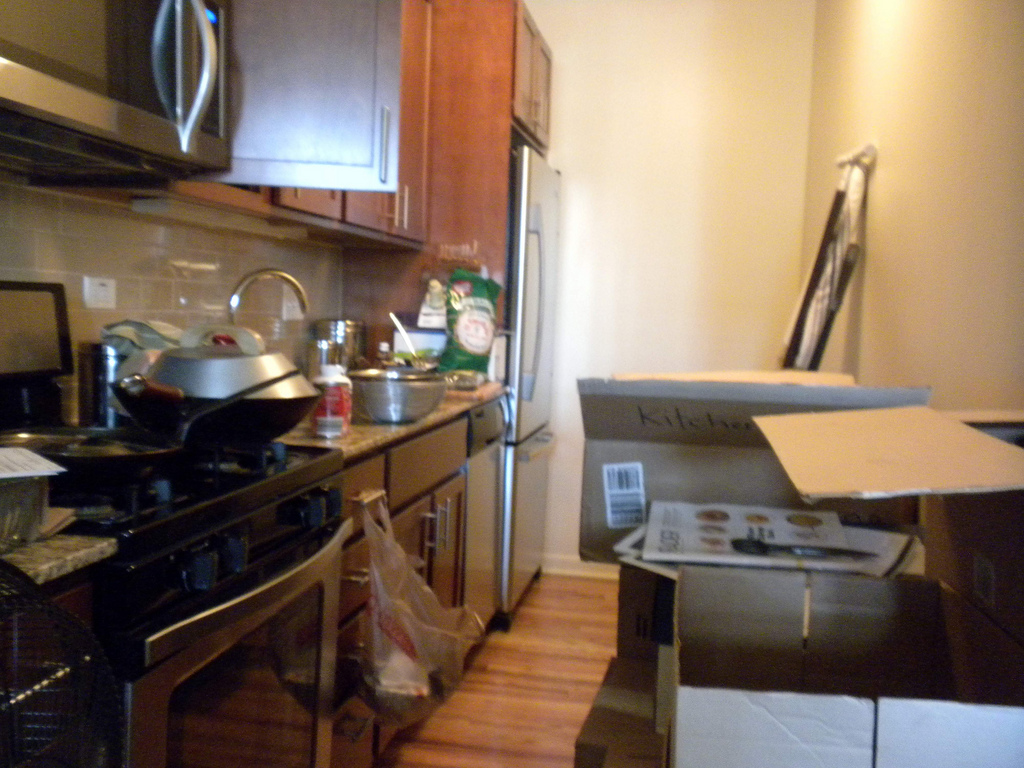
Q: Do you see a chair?
A: No, there are no chairs.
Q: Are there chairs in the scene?
A: No, there are no chairs.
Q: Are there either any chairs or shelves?
A: No, there are no chairs or shelves.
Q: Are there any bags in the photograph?
A: Yes, there is a bag.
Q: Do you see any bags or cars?
A: Yes, there is a bag.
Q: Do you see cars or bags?
A: Yes, there is a bag.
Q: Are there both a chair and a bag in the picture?
A: No, there is a bag but no chairs.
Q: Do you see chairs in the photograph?
A: No, there are no chairs.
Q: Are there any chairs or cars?
A: No, there are no chairs or cars.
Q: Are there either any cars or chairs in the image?
A: No, there are no chairs or cars.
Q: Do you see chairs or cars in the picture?
A: No, there are no chairs or cars.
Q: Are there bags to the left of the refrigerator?
A: Yes, there is a bag to the left of the refrigerator.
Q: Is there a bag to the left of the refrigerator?
A: Yes, there is a bag to the left of the refrigerator.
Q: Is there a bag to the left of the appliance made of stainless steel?
A: Yes, there is a bag to the left of the refrigerator.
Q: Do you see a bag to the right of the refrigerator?
A: No, the bag is to the left of the refrigerator.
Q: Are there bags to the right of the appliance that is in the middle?
A: No, the bag is to the left of the refrigerator.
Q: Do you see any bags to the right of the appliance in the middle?
A: No, the bag is to the left of the refrigerator.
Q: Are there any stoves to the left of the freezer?
A: No, there is a bag to the left of the freezer.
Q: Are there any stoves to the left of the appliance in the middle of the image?
A: No, there is a bag to the left of the freezer.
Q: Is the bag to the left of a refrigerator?
A: Yes, the bag is to the left of a refrigerator.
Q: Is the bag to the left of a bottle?
A: No, the bag is to the left of a refrigerator.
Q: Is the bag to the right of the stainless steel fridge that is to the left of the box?
A: No, the bag is to the left of the refrigerator.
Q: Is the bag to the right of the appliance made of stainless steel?
A: No, the bag is to the left of the refrigerator.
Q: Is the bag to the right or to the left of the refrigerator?
A: The bag is to the left of the refrigerator.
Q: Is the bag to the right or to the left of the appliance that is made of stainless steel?
A: The bag is to the left of the refrigerator.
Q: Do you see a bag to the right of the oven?
A: Yes, there is a bag to the right of the oven.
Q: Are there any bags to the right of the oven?
A: Yes, there is a bag to the right of the oven.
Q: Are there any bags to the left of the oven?
A: No, the bag is to the right of the oven.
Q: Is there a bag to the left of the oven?
A: No, the bag is to the right of the oven.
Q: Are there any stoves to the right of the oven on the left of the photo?
A: No, there is a bag to the right of the oven.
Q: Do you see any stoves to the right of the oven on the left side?
A: No, there is a bag to the right of the oven.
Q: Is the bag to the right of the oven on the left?
A: Yes, the bag is to the right of the oven.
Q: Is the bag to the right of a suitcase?
A: No, the bag is to the right of the oven.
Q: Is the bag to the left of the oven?
A: No, the bag is to the right of the oven.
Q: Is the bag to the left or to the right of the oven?
A: The bag is to the right of the oven.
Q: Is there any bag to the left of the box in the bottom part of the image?
A: Yes, there is a bag to the left of the box.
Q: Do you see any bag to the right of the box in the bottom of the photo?
A: No, the bag is to the left of the box.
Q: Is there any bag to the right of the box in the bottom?
A: No, the bag is to the left of the box.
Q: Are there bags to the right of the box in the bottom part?
A: No, the bag is to the left of the box.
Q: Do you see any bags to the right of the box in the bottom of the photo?
A: No, the bag is to the left of the box.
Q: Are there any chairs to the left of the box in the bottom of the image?
A: No, there is a bag to the left of the box.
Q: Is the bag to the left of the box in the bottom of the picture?
A: Yes, the bag is to the left of the box.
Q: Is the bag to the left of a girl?
A: No, the bag is to the left of the box.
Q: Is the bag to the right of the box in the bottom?
A: No, the bag is to the left of the box.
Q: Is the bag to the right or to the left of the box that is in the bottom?
A: The bag is to the left of the box.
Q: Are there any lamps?
A: No, there are no lamps.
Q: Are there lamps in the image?
A: No, there are no lamps.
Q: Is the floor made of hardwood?
A: Yes, the floor is made of hardwood.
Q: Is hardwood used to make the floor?
A: Yes, the floor is made of hardwood.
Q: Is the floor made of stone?
A: No, the floor is made of hardwood.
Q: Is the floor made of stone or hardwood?
A: The floor is made of hardwood.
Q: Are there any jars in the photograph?
A: No, there are no jars.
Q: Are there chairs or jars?
A: No, there are no jars or chairs.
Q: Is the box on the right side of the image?
A: Yes, the box is on the right of the image.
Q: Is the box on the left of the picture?
A: No, the box is on the right of the image.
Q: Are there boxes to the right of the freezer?
A: Yes, there is a box to the right of the freezer.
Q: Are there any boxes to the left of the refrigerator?
A: No, the box is to the right of the refrigerator.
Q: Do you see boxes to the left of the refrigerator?
A: No, the box is to the right of the refrigerator.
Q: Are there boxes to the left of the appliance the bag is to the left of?
A: No, the box is to the right of the refrigerator.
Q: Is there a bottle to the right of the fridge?
A: No, there is a box to the right of the fridge.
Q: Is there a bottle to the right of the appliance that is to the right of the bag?
A: No, there is a box to the right of the fridge.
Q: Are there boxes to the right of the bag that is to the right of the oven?
A: Yes, there is a box to the right of the bag.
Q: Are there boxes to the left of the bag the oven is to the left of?
A: No, the box is to the right of the bag.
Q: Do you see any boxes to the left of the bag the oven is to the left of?
A: No, the box is to the right of the bag.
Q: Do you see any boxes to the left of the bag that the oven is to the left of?
A: No, the box is to the right of the bag.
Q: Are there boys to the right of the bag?
A: No, there is a box to the right of the bag.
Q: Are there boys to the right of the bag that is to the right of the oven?
A: No, there is a box to the right of the bag.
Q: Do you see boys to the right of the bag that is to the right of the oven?
A: No, there is a box to the right of the bag.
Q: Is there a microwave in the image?
A: Yes, there is a microwave.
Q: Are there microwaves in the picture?
A: Yes, there is a microwave.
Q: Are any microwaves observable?
A: Yes, there is a microwave.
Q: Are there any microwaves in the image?
A: Yes, there is a microwave.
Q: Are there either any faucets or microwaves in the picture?
A: Yes, there is a microwave.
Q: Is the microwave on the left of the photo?
A: Yes, the microwave is on the left of the image.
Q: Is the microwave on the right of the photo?
A: No, the microwave is on the left of the image.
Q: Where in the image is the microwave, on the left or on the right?
A: The microwave is on the left of the image.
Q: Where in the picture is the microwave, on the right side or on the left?
A: The microwave is on the left of the image.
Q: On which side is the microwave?
A: The microwave is on the left of the image.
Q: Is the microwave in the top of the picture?
A: Yes, the microwave is in the top of the image.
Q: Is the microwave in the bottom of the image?
A: No, the microwave is in the top of the image.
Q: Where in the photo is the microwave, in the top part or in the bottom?
A: The microwave is in the top of the image.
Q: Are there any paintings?
A: No, there are no paintings.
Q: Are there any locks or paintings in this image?
A: No, there are no paintings or locks.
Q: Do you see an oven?
A: Yes, there is an oven.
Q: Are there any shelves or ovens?
A: Yes, there is an oven.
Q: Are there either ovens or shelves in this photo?
A: Yes, there is an oven.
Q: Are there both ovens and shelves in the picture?
A: No, there is an oven but no shelves.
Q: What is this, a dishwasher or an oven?
A: This is an oven.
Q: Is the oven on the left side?
A: Yes, the oven is on the left of the image.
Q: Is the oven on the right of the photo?
A: No, the oven is on the left of the image.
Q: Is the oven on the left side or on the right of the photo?
A: The oven is on the left of the image.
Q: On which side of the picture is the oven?
A: The oven is on the left of the image.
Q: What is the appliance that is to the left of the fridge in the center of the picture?
A: The appliance is an oven.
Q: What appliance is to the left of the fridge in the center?
A: The appliance is an oven.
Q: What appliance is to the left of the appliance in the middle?
A: The appliance is an oven.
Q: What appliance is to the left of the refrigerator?
A: The appliance is an oven.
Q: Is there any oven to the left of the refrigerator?
A: Yes, there is an oven to the left of the refrigerator.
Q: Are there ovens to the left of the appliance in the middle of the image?
A: Yes, there is an oven to the left of the refrigerator.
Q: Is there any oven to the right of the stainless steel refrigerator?
A: No, the oven is to the left of the freezer.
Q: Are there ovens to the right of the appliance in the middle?
A: No, the oven is to the left of the freezer.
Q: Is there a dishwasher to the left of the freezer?
A: No, there is an oven to the left of the freezer.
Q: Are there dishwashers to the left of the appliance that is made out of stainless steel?
A: No, there is an oven to the left of the freezer.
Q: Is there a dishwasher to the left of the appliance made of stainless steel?
A: No, there is an oven to the left of the freezer.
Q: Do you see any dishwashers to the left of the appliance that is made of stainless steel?
A: No, there is an oven to the left of the freezer.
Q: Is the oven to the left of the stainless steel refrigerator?
A: Yes, the oven is to the left of the freezer.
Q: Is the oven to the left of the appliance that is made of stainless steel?
A: Yes, the oven is to the left of the freezer.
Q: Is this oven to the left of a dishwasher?
A: No, the oven is to the left of the freezer.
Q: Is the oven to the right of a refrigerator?
A: No, the oven is to the left of a refrigerator.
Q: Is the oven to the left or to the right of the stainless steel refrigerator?
A: The oven is to the left of the refrigerator.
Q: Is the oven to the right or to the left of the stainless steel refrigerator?
A: The oven is to the left of the refrigerator.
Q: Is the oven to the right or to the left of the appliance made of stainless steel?
A: The oven is to the left of the refrigerator.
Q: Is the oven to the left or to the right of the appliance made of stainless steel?
A: The oven is to the left of the refrigerator.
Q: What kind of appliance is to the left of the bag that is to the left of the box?
A: The appliance is an oven.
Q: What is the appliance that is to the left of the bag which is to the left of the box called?
A: The appliance is an oven.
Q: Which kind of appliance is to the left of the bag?
A: The appliance is an oven.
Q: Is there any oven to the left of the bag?
A: Yes, there is an oven to the left of the bag.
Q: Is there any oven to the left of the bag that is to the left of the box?
A: Yes, there is an oven to the left of the bag.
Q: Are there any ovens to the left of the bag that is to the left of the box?
A: Yes, there is an oven to the left of the bag.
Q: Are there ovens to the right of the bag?
A: No, the oven is to the left of the bag.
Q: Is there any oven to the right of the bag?
A: No, the oven is to the left of the bag.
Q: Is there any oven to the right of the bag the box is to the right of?
A: No, the oven is to the left of the bag.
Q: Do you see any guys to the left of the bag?
A: No, there is an oven to the left of the bag.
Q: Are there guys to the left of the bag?
A: No, there is an oven to the left of the bag.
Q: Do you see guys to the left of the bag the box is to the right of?
A: No, there is an oven to the left of the bag.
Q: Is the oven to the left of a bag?
A: Yes, the oven is to the left of a bag.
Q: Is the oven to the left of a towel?
A: No, the oven is to the left of a bag.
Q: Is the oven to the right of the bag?
A: No, the oven is to the left of the bag.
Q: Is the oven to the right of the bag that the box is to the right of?
A: No, the oven is to the left of the bag.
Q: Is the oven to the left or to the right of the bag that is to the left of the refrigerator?
A: The oven is to the left of the bag.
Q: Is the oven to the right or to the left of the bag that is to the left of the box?
A: The oven is to the left of the bag.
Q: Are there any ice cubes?
A: No, there are no ice cubes.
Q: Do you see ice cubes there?
A: No, there are no ice cubes.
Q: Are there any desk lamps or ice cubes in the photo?
A: No, there are no ice cubes or desk lamps.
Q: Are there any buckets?
A: No, there are no buckets.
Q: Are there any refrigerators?
A: Yes, there is a refrigerator.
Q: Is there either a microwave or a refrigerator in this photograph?
A: Yes, there is a refrigerator.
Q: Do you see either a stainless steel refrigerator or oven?
A: Yes, there is a stainless steel refrigerator.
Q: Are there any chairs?
A: No, there are no chairs.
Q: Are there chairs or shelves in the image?
A: No, there are no chairs or shelves.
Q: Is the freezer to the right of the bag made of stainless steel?
A: Yes, the freezer is made of stainless steel.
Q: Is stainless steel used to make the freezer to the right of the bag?
A: Yes, the freezer is made of stainless steel.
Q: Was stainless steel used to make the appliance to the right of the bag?
A: Yes, the freezer is made of stainless steel.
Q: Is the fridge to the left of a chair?
A: No, the fridge is to the left of a box.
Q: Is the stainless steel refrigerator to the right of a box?
A: No, the refrigerator is to the left of a box.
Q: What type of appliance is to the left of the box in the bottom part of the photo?
A: The appliance is a refrigerator.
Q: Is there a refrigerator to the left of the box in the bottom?
A: Yes, there is a refrigerator to the left of the box.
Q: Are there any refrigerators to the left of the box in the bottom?
A: Yes, there is a refrigerator to the left of the box.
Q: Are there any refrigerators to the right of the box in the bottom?
A: No, the refrigerator is to the left of the box.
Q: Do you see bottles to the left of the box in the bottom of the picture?
A: No, there is a refrigerator to the left of the box.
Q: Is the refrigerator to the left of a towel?
A: No, the refrigerator is to the left of a box.